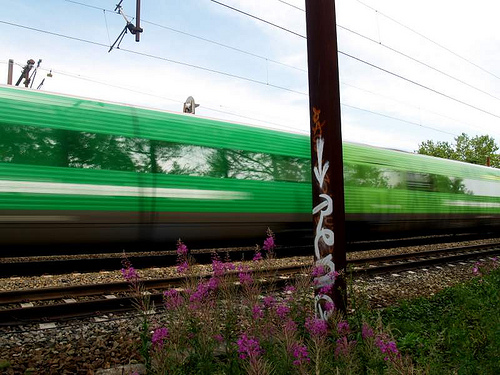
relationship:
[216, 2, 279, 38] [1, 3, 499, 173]
cloud in sky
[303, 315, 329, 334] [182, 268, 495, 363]
flower by grass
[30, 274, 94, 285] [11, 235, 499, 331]
rocks by tracks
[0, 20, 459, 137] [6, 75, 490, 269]
power line over train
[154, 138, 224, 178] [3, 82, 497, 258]
window on a train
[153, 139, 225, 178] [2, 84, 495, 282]
window on a train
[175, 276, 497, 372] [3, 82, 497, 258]
grass next to train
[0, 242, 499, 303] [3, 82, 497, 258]
tracks next to train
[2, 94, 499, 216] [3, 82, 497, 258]
side of train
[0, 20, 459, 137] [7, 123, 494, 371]
power line above land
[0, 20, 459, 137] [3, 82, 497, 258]
power line over train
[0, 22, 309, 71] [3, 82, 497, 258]
power line over train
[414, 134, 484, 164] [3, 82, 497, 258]
trees behind train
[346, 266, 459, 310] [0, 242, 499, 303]
rocks by tracks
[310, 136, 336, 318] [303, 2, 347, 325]
graffiti on pole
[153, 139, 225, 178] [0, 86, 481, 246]
window on train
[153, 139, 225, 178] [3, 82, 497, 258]
window on train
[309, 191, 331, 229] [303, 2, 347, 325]
letter on pole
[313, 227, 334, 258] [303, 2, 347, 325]
letter on pole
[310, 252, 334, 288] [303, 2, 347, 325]
letter on pole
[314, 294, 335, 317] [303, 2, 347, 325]
letter on pole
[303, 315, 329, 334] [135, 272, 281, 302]
flower by railroad track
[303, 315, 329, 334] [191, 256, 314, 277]
flower by railroad track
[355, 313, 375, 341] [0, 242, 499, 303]
flower by tracks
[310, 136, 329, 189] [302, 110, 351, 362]
graffiti on pole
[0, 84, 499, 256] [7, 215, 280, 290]
train on tracks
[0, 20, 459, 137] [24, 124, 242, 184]
power line hang above train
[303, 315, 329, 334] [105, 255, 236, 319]
flower next to tracks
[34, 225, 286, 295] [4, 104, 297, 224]
tracks next to train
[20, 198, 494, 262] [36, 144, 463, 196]
shadow of train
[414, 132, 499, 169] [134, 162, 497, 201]
trees behind train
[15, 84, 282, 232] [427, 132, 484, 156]
train in front of trees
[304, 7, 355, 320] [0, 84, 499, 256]
pole in front of train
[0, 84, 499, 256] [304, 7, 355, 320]
train behind pole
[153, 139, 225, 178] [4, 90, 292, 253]
window on a train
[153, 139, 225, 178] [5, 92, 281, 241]
window on a train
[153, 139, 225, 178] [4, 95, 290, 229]
window on a train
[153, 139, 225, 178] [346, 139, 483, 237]
window on a train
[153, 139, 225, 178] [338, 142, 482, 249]
window on a train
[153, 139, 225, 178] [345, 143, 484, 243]
window on a train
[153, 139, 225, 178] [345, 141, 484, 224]
window on a train